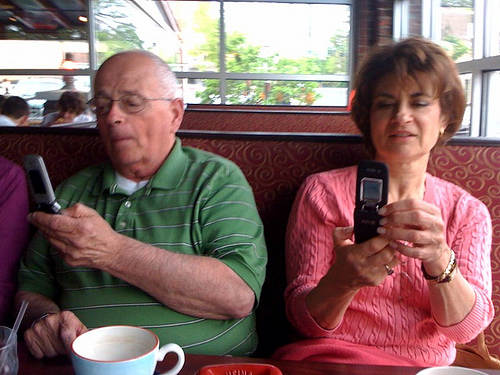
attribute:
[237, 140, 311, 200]
restaurant booth — patterned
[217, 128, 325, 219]
booth — red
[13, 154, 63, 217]
phone — flip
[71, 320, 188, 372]
cup — coffee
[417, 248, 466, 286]
bracelet — woman's 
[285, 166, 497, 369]
sweater — pink, one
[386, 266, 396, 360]
design — vertical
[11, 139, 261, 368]
shirt — green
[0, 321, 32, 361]
rim — glass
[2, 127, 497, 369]
bench — red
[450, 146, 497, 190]
design — gold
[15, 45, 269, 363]
man — one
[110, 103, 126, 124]
nose — man's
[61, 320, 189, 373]
cup — one, white, coffee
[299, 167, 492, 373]
shirt — one, pink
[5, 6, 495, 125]
window — one, huge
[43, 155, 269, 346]
shirt — one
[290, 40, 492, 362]
lady — one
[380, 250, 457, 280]
jewelry — some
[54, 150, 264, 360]
shirt — green 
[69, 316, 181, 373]
mug — white, coffee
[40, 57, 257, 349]
man — one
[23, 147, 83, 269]
phone — cell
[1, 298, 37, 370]
glass — one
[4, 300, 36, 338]
straw — plastic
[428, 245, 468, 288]
wrist — human, female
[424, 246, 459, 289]
bracelet — one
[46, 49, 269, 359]
man — one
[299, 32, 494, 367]
woman — one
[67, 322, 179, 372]
mug — coffee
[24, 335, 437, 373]
table — one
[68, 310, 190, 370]
mug — one, blue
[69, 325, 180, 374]
cup — white and blue , empty 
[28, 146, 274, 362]
shirt — green 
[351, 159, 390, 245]
phone — flip